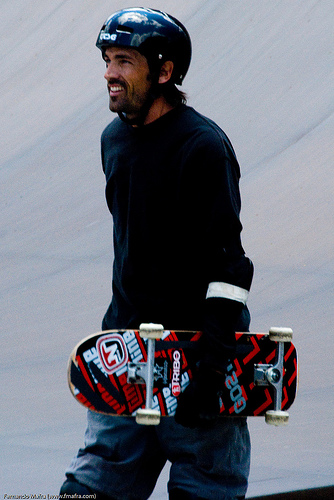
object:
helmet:
[95, 7, 192, 85]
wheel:
[139, 322, 164, 337]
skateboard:
[66, 322, 298, 425]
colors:
[68, 330, 296, 416]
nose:
[104, 60, 121, 82]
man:
[59, 6, 255, 498]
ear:
[159, 60, 174, 83]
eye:
[118, 58, 134, 66]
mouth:
[107, 82, 126, 97]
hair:
[162, 80, 188, 108]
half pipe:
[1, 2, 333, 499]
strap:
[115, 67, 157, 128]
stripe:
[206, 281, 249, 307]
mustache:
[106, 77, 129, 96]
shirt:
[101, 102, 254, 374]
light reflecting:
[111, 7, 174, 28]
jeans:
[59, 410, 252, 500]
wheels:
[268, 326, 293, 343]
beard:
[107, 81, 150, 114]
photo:
[0, 0, 334, 499]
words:
[122, 384, 136, 402]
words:
[234, 397, 247, 413]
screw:
[128, 377, 138, 385]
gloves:
[176, 366, 225, 429]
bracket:
[127, 361, 147, 384]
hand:
[177, 367, 223, 430]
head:
[95, 1, 193, 112]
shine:
[96, 6, 192, 51]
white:
[141, 420, 158, 426]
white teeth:
[110, 86, 121, 91]